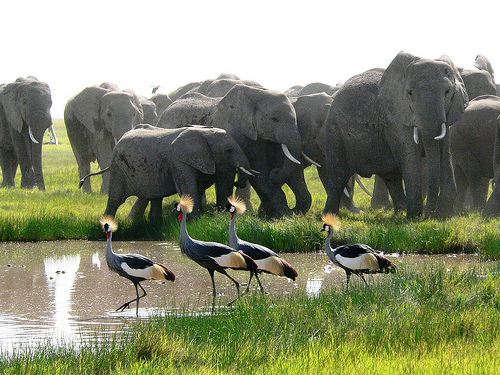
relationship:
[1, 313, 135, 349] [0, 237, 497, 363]
ripples on water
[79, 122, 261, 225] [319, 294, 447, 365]
elephant on grass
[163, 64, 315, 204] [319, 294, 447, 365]
elephant on grass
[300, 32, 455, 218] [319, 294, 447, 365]
elephant on grass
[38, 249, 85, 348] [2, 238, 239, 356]
reflection on water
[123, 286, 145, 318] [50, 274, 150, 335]
leg in water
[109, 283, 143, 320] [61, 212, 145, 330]
leg in air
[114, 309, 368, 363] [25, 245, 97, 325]
grass by water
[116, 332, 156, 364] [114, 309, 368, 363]
stone in grass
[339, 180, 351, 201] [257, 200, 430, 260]
tusks almost touching ground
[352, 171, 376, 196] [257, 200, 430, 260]
tusks almost touching ground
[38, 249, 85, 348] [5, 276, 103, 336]
reflection in water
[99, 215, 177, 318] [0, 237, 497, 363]
bird waking in water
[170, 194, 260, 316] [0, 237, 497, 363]
bird waking in water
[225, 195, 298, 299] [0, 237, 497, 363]
bird waking in water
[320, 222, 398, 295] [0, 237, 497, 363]
bird waking in water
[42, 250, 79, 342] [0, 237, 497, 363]
reflection on water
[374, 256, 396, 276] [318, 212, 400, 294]
tail feathers on bird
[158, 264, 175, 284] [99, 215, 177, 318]
tail feathers on bird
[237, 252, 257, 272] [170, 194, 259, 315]
tail feathers on bird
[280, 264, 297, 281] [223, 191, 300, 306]
tail feathers on bird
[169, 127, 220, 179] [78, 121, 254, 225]
ear on elephant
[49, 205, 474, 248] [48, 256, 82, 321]
grass above water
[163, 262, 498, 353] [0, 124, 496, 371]
grass on ground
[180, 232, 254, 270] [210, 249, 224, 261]
wing has edge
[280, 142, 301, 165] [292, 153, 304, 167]
tusk has tip